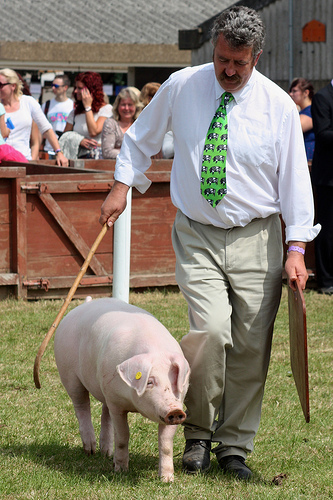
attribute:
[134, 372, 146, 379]
tag — yellow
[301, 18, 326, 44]
object — orange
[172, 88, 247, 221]
necktie — green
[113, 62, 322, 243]
shirt — white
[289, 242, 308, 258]
wristband — purple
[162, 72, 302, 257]
shirt — white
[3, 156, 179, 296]
fence — wooden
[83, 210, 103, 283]
stick — brown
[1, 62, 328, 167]
spectators — in background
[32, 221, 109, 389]
stick — extended out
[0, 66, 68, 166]
lady — blue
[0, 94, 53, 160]
shirt — white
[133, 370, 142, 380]
tag — yellow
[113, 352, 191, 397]
ears — floppy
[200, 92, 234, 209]
tie — decorated, green, neck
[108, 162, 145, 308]
pole — white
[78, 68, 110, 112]
hair — red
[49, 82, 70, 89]
shades — blue lenses 